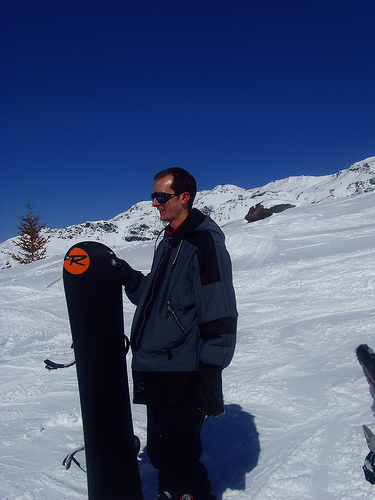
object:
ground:
[267, 219, 346, 432]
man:
[117, 167, 239, 496]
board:
[61, 242, 146, 499]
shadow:
[206, 402, 262, 499]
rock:
[246, 201, 299, 224]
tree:
[15, 189, 53, 270]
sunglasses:
[150, 189, 171, 205]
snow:
[285, 302, 341, 365]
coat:
[133, 214, 239, 372]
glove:
[111, 254, 143, 294]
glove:
[198, 364, 227, 420]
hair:
[156, 166, 195, 194]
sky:
[0, 2, 371, 236]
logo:
[66, 245, 89, 276]